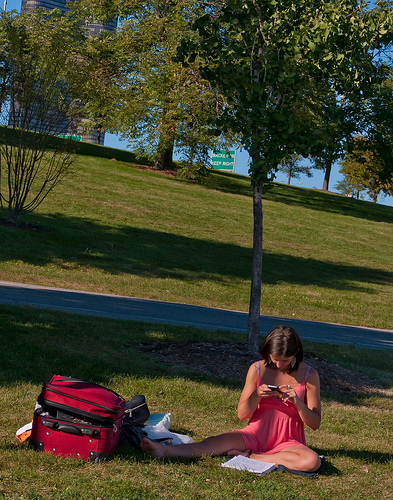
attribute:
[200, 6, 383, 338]
tree — Tall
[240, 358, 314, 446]
dress — pink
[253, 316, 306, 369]
hair — brown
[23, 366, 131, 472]
luggage — red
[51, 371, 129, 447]
suitcase — red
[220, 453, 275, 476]
book — Open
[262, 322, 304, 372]
hair — short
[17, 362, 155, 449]
luggage — red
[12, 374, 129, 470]
luggage bag — red, opened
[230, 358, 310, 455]
sundress — pink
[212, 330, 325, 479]
dress — pink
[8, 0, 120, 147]
building — large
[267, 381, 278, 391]
phone — cellphone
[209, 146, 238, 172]
sign — green, direction sign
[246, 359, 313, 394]
bra — white